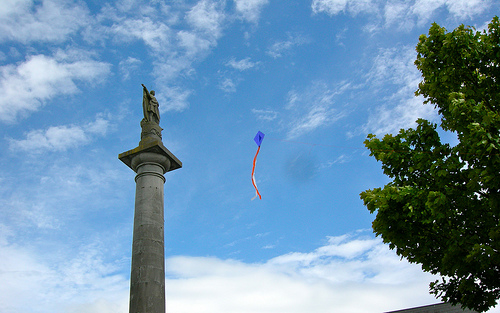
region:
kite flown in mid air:
[227, 114, 284, 211]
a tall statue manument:
[99, 57, 197, 311]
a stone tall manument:
[114, 67, 197, 308]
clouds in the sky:
[7, 7, 347, 84]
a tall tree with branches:
[342, 17, 497, 300]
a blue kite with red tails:
[239, 121, 279, 206]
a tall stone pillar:
[127, 174, 170, 311]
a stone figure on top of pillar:
[140, 79, 170, 141]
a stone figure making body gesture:
[127, 77, 169, 139]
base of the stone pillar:
[111, 139, 190, 173]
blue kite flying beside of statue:
[250, 127, 262, 142]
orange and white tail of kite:
[245, 140, 260, 195]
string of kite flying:
[260, 135, 335, 140]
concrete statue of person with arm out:
[140, 80, 160, 120]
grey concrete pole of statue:
[120, 140, 180, 305]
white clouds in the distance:
[207, 252, 279, 297]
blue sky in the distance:
[297, 177, 349, 220]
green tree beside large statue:
[367, 19, 497, 245]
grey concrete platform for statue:
[117, 141, 186, 173]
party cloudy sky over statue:
[54, 12, 226, 81]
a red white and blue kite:
[252, 128, 267, 200]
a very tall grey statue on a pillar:
[118, 80, 185, 311]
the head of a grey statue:
[149, 87, 155, 97]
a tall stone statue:
[142, 83, 162, 125]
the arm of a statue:
[137, 81, 152, 100]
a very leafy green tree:
[357, 16, 498, 311]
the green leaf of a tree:
[392, 148, 398, 155]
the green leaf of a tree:
[377, 149, 385, 158]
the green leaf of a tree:
[379, 191, 385, 197]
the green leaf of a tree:
[404, 184, 409, 192]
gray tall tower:
[109, 48, 179, 311]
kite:
[244, 126, 261, 190]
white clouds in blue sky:
[17, 17, 90, 93]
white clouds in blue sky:
[321, 66, 348, 94]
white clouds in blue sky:
[292, 237, 321, 270]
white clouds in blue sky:
[215, 245, 256, 286]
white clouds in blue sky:
[55, 183, 72, 202]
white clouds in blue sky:
[62, 241, 88, 263]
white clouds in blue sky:
[49, 116, 71, 144]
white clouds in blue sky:
[118, 37, 179, 62]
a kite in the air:
[197, 93, 362, 230]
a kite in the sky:
[222, 93, 310, 251]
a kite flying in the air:
[216, 106, 296, 233]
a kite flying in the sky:
[237, 119, 290, 187]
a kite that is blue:
[226, 100, 287, 272]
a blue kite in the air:
[222, 120, 346, 239]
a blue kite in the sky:
[223, 105, 275, 219]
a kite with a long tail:
[239, 111, 286, 208]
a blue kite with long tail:
[233, 111, 320, 261]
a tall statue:
[77, 38, 214, 305]